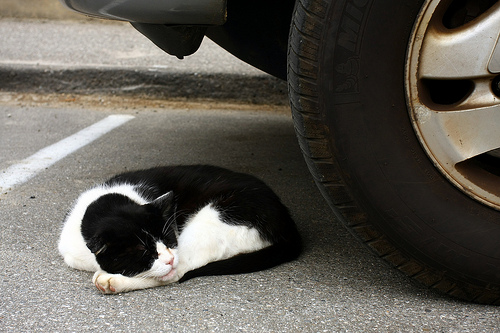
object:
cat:
[57, 164, 305, 295]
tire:
[286, 0, 500, 307]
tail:
[180, 240, 304, 283]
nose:
[166, 256, 173, 266]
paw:
[92, 271, 127, 298]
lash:
[161, 208, 188, 239]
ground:
[0, 13, 500, 331]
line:
[0, 113, 137, 197]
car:
[61, 1, 500, 305]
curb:
[0, 60, 289, 118]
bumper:
[64, 0, 230, 60]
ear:
[147, 191, 175, 217]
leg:
[156, 217, 235, 284]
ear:
[95, 244, 108, 256]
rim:
[399, 4, 500, 202]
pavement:
[4, 17, 500, 327]